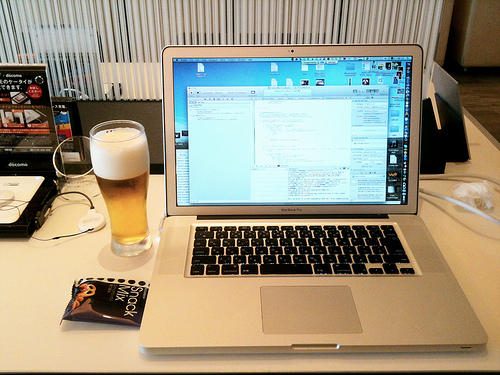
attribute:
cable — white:
[377, 168, 497, 241]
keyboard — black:
[215, 191, 419, 292]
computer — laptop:
[139, 45, 488, 354]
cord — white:
[419, 171, 499, 230]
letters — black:
[271, 206, 306, 218]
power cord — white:
[418, 185, 498, 225]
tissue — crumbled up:
[436, 171, 490, 213]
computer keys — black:
[183, 222, 416, 277]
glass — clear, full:
[82, 110, 155, 262]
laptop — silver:
[132, 41, 491, 361]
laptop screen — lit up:
[172, 57, 410, 202]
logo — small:
[256, 202, 314, 214]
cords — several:
[39, 141, 93, 245]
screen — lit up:
[166, 51, 422, 211]